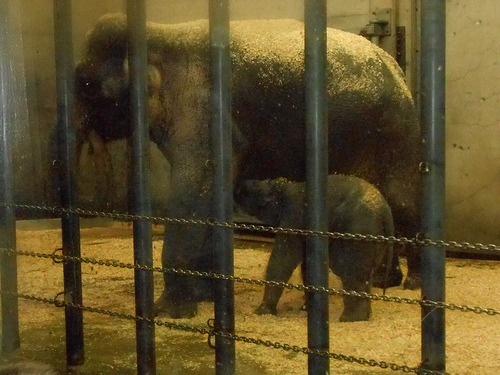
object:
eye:
[83, 81, 92, 88]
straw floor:
[447, 257, 497, 303]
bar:
[50, 0, 83, 370]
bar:
[208, 4, 234, 372]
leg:
[332, 271, 372, 310]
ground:
[346, 157, 392, 196]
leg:
[383, 161, 446, 277]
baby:
[231, 172, 396, 323]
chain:
[0, 246, 497, 313]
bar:
[418, 1, 446, 373]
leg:
[162, 141, 213, 289]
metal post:
[0, 7, 27, 358]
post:
[118, 3, 161, 375]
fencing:
[3, 196, 498, 371]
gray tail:
[383, 237, 396, 297]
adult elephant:
[46, 12, 434, 318]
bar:
[299, 1, 335, 371]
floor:
[97, 103, 158, 135]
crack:
[448, 34, 488, 81]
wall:
[438, 3, 496, 259]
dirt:
[146, 16, 411, 97]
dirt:
[287, 174, 388, 208]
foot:
[253, 301, 278, 316]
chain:
[0, 199, 499, 259]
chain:
[3, 285, 447, 373]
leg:
[261, 228, 307, 299]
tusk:
[80, 140, 91, 172]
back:
[275, 176, 397, 223]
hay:
[363, 184, 381, 209]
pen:
[2, 4, 498, 372]